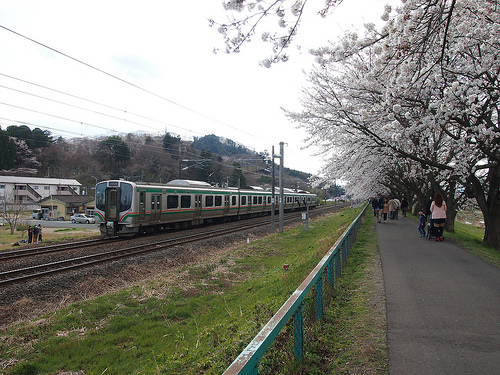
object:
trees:
[93, 135, 132, 178]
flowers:
[393, 104, 401, 113]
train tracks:
[41, 247, 146, 278]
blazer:
[430, 199, 447, 219]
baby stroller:
[426, 219, 446, 242]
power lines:
[0, 72, 47, 87]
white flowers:
[395, 133, 402, 140]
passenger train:
[93, 178, 319, 238]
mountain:
[200, 132, 253, 159]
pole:
[279, 143, 285, 232]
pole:
[272, 145, 274, 234]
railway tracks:
[30, 257, 76, 273]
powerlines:
[78, 97, 105, 107]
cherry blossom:
[213, 47, 218, 54]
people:
[417, 210, 426, 238]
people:
[28, 225, 33, 244]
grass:
[26, 363, 40, 370]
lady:
[430, 193, 447, 242]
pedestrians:
[384, 198, 390, 223]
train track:
[237, 218, 269, 231]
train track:
[153, 234, 201, 249]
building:
[35, 194, 93, 220]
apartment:
[1, 176, 82, 203]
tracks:
[0, 247, 45, 259]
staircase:
[27, 183, 42, 200]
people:
[388, 197, 398, 220]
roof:
[53, 194, 94, 202]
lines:
[0, 23, 77, 60]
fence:
[226, 273, 322, 374]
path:
[370, 200, 499, 375]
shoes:
[435, 238, 439, 242]